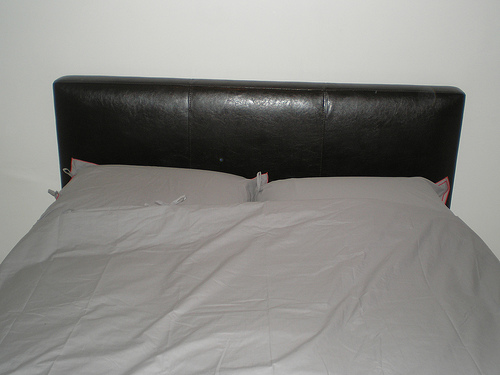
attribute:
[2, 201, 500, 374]
bedsheet — grey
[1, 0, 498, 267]
wall — white, clean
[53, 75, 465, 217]
head board — leather, brown, big, black, square, plain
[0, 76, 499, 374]
bed — made, neat, double size, empty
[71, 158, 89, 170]
corner — red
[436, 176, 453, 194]
corner — red